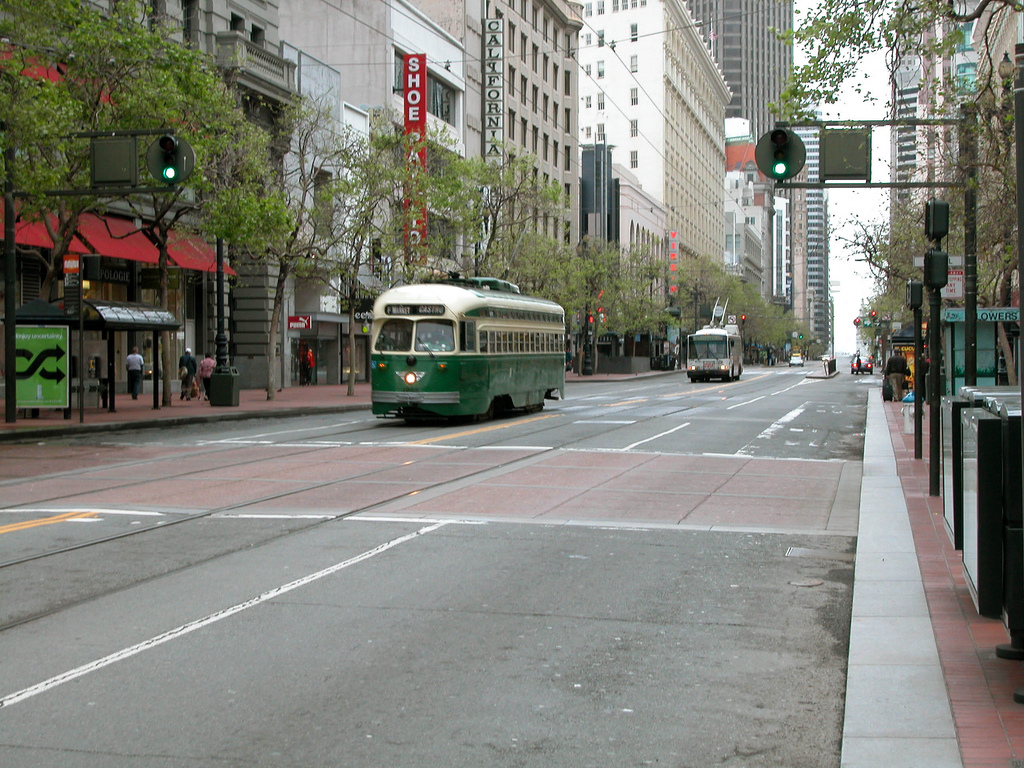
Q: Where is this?
A: This is at the road.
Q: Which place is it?
A: It is a road.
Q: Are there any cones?
A: No, there are no cones.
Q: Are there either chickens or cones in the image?
A: No, there are no cones or chickens.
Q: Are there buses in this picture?
A: Yes, there is a bus.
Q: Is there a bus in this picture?
A: Yes, there is a bus.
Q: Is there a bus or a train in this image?
A: Yes, there is a bus.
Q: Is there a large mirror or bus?
A: Yes, there is a large bus.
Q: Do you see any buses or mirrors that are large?
A: Yes, the bus is large.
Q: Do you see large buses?
A: Yes, there is a large bus.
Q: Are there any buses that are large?
A: Yes, there is a bus that is large.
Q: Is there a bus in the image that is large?
A: Yes, there is a bus that is large.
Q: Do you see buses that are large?
A: Yes, there is a bus that is large.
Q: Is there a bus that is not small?
A: Yes, there is a large bus.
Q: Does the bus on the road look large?
A: Yes, the bus is large.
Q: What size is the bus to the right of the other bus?
A: The bus is large.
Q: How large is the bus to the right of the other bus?
A: The bus is large.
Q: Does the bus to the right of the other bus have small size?
A: No, the bus is large.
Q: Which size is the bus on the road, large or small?
A: The bus is large.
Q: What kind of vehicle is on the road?
A: The vehicle is a bus.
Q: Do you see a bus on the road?
A: Yes, there is a bus on the road.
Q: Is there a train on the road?
A: No, there is a bus on the road.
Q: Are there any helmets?
A: No, there are no helmets.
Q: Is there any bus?
A: Yes, there is a bus.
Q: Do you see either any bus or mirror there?
A: Yes, there is a bus.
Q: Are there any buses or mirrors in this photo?
A: Yes, there is a bus.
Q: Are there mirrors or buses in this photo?
A: Yes, there is a bus.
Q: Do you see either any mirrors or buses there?
A: Yes, there is a bus.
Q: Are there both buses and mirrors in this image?
A: No, there is a bus but no mirrors.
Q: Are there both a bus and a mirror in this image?
A: No, there is a bus but no mirrors.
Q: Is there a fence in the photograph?
A: No, there are no fences.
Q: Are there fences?
A: No, there are no fences.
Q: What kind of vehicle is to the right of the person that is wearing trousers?
A: The vehicle is a bus.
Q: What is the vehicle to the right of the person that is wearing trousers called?
A: The vehicle is a bus.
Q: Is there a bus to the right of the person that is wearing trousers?
A: Yes, there is a bus to the right of the person.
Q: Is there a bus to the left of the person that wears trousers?
A: No, the bus is to the right of the person.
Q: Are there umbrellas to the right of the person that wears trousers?
A: No, there is a bus to the right of the person.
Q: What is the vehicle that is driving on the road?
A: The vehicle is a bus.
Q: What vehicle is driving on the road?
A: The vehicle is a bus.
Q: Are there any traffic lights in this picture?
A: Yes, there is a traffic light.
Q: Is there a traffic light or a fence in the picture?
A: Yes, there is a traffic light.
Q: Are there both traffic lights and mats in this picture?
A: No, there is a traffic light but no mats.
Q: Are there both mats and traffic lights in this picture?
A: No, there is a traffic light but no mats.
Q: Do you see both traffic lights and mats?
A: No, there is a traffic light but no mats.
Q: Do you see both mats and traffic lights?
A: No, there is a traffic light but no mats.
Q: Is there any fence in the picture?
A: No, there are no fences.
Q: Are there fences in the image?
A: No, there are no fences.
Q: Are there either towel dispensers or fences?
A: No, there are no fences or towel dispensers.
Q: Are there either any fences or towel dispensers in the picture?
A: No, there are no fences or towel dispensers.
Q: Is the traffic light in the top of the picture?
A: Yes, the traffic light is in the top of the image.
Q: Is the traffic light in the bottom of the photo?
A: No, the traffic light is in the top of the image.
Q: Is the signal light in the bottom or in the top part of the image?
A: The signal light is in the top of the image.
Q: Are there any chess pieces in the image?
A: No, there are no chess pieces.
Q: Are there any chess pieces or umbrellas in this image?
A: No, there are no chess pieces or umbrellas.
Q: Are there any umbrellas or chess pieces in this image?
A: No, there are no chess pieces or umbrellas.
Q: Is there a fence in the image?
A: No, there are no fences.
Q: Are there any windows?
A: Yes, there are windows.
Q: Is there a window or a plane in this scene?
A: Yes, there are windows.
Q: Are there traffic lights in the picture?
A: Yes, there is a traffic light.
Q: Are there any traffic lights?
A: Yes, there is a traffic light.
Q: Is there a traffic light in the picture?
A: Yes, there is a traffic light.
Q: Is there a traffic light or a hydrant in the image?
A: Yes, there is a traffic light.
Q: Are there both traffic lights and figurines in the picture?
A: No, there is a traffic light but no figurines.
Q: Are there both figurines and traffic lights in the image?
A: No, there is a traffic light but no figurines.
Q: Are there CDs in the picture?
A: No, there are no cds.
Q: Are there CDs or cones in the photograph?
A: No, there are no CDs or cones.